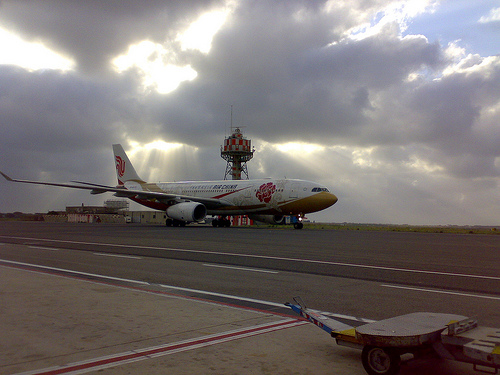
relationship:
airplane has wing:
[7, 142, 338, 232] [1, 171, 226, 207]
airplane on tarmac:
[7, 142, 338, 232] [161, 224, 414, 284]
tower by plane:
[206, 122, 267, 175] [80, 149, 333, 232]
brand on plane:
[255, 181, 277, 204] [23, 93, 400, 258]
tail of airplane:
[111, 141, 143, 183] [7, 142, 338, 232]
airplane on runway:
[7, 142, 338, 232] [0, 224, 498, 294]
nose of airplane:
[322, 188, 342, 206] [7, 142, 338, 232]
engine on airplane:
[173, 187, 239, 224] [7, 142, 338, 232]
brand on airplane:
[255, 181, 277, 204] [7, 142, 338, 232]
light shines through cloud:
[121, 128, 341, 184] [2, 3, 227, 65]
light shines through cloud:
[121, 128, 341, 184] [0, 61, 163, 146]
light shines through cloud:
[121, 128, 341, 184] [144, 3, 497, 178]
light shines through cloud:
[121, 128, 341, 184] [136, 146, 497, 228]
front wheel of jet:
[293, 222, 305, 229] [3, 142, 338, 227]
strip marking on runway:
[2, 234, 499, 280] [0, 217, 497, 373]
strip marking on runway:
[26, 243, 60, 251] [0, 217, 497, 373]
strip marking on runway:
[92, 250, 142, 259] [0, 217, 497, 373]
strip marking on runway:
[201, 261, 278, 273] [0, 217, 497, 373]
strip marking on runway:
[379, 282, 499, 300] [0, 217, 497, 373]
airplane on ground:
[7, 142, 338, 226] [121, 224, 453, 278]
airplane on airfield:
[7, 142, 338, 232] [1, 196, 499, 372]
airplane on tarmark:
[7, 142, 338, 232] [5, 213, 499, 375]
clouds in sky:
[207, 52, 335, 120] [416, 20, 463, 48]